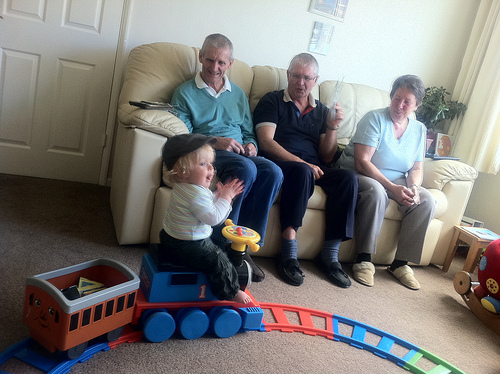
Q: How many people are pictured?
A: Four.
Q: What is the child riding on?
A: A toy train.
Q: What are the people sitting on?
A: A couch.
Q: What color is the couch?
A: Tan.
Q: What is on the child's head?
A: A hat.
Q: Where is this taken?
A: A living room.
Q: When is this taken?
A: Daytime.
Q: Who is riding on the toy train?
A: A child.